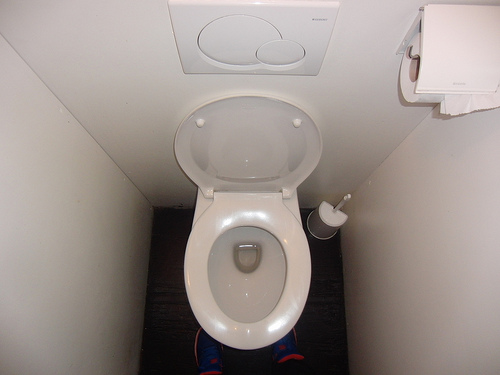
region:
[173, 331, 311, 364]
the shoes are blue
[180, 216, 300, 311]
the toilet is white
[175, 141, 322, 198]
the toilet seat is up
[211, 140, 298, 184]
there is a toilet reflection on the toilet seat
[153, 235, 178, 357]
the floor is made of wood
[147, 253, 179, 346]
the floor is brown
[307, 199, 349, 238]
the toilet brush is white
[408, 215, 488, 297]
the walls are white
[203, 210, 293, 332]
there is light reflection on the seat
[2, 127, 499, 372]
the photo is indoors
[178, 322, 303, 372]
A pair of blue and red sneakers.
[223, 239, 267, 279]
Water at the bottom of a toilet.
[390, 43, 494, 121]
A roll of toilet paper on the wall.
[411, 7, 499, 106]
A cover for the roll of toilet paper.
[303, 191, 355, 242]
A toilet bowl brush.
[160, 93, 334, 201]
The lid to a toilet.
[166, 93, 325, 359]
A small white toilet on the ground.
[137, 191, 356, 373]
A piece of grey carpet under the toilet.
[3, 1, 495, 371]
A really tiny bathroom.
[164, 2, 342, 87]
A white panel on the wall.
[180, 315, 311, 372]
Blue and red shoes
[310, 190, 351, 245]
a white toilet brush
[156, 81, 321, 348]
a white toilet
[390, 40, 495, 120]
a roll of toilet paper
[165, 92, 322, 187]
a toilet bowl cover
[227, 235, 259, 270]
the water in a toilet bowl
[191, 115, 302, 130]
toilet bowl cover stoppers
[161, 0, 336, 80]
Wall mounted toilet flushing buttons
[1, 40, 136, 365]
The left wall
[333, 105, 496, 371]
The right wall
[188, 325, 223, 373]
Blue and red sneaker in front of a toilet.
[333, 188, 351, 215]
White handle of a toilet brush in the corner of a bathroom.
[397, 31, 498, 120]
Toilet paper roll up on the wall.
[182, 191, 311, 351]
Shiny white toilet seat in a small bathroom.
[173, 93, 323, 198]
White toilet lid that is up on a toilet.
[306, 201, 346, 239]
Toilet scrubbing brush holder that is sitting in a corner.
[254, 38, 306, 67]
Small circle on the wall above the toilet.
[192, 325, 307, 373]
Blue and red sneakers in front of a toilet.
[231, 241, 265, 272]
Inside of a white toilet that hasn't been used.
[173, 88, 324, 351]
White shiny toilet in a small bathroom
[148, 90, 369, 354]
a toilet with the lid up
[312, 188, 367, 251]
a toilet cleaning brush in a container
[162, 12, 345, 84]
toilet seat covers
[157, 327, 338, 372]
somebody's feet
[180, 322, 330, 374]
the feet have black shoes with red trim on them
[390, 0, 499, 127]
toilet paper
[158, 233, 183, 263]
the floor is black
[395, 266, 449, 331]
the wall is grey or off white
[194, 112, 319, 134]
the lid has little feet on it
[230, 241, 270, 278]
the water level is low in the bowl